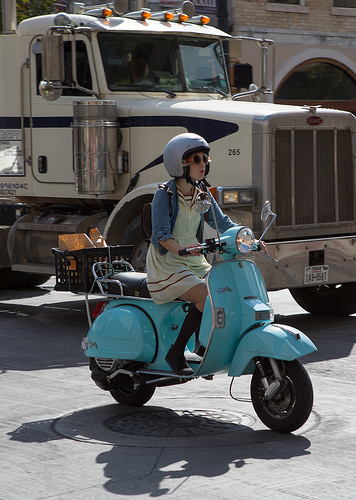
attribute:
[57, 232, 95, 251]
paper bag — brown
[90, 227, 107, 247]
paper bag — brown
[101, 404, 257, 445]
manhole cover — black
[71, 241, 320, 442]
scooter — blue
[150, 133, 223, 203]
girl — driving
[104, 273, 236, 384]
scooter — blue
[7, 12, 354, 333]
truck — white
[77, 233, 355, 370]
bike — blue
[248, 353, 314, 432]
tire — black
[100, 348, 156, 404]
tire — black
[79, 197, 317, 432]
moped — blue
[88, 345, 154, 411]
tire — black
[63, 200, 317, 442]
bike — blue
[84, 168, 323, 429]
bike — motorized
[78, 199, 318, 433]
scooter — blue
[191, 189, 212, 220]
mirror — silver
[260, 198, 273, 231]
mirror — silver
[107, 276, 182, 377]
bike — blue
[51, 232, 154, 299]
basket — Black 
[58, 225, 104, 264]
paper sacks — Brown 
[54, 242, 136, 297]
crate — Black 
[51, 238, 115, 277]
basket — black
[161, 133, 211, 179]
helmet — Gray 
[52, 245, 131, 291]
basket — black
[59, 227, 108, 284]
paper bags — brown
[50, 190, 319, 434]
moped — blue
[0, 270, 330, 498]
road — concrete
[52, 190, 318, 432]
bike — blue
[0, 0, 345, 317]
truck — white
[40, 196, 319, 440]
scooter — blue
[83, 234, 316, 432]
scooter — blue